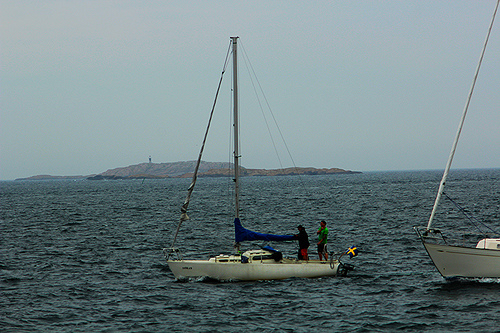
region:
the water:
[353, 182, 395, 225]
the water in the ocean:
[56, 220, 136, 291]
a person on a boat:
[297, 226, 313, 261]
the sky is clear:
[288, 75, 358, 123]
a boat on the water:
[135, 58, 370, 317]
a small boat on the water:
[160, 74, 387, 329]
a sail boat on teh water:
[157, 72, 363, 327]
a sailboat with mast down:
[169, 47, 389, 327]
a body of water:
[75, 224, 207, 309]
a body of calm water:
[24, 198, 196, 331]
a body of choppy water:
[39, 180, 243, 325]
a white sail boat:
[174, 236, 354, 320]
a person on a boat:
[262, 213, 309, 283]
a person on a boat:
[316, 213, 337, 275]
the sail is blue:
[228, 213, 309, 246]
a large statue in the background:
[146, 152, 155, 164]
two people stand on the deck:
[288, 215, 335, 267]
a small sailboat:
[164, 32, 364, 289]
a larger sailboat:
[413, 27, 499, 292]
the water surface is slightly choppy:
[1, 174, 499, 329]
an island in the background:
[13, 155, 366, 185]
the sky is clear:
[0, 27, 499, 184]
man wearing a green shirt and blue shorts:
[313, 218, 333, 262]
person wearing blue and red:
[289, 217, 312, 262]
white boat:
[128, 238, 338, 282]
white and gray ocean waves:
[117, 289, 139, 303]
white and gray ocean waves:
[75, 232, 109, 257]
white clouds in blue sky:
[387, 22, 455, 47]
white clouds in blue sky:
[20, 22, 81, 70]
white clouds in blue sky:
[54, 132, 98, 147]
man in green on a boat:
[316, 216, 331, 262]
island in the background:
[11, 156, 366, 181]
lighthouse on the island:
[147, 153, 153, 165]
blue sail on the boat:
[231, 215, 299, 244]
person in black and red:
[292, 220, 313, 264]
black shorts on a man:
[317, 239, 328, 253]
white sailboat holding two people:
[163, 248, 345, 284]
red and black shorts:
[295, 246, 309, 261]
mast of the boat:
[227, 29, 247, 256]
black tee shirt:
[296, 228, 312, 250]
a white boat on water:
[118, 255, 351, 285]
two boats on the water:
[145, 191, 498, 316]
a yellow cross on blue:
[341, 238, 368, 259]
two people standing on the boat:
[278, 208, 342, 260]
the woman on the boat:
[289, 225, 314, 266]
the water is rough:
[39, 176, 124, 294]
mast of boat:
[224, 24, 246, 252]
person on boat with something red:
[293, 220, 314, 262]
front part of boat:
[164, 241, 219, 292]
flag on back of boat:
[349, 245, 361, 259]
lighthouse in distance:
[145, 148, 155, 167]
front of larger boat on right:
[418, 202, 488, 289]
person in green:
[317, 215, 331, 257]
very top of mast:
[217, 26, 257, 62]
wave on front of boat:
[172, 270, 220, 289]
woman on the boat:
[288, 216, 317, 274]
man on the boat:
[313, 219, 338, 257]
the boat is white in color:
[180, 253, 335, 279]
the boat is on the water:
[158, 222, 354, 289]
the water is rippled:
[37, 178, 144, 289]